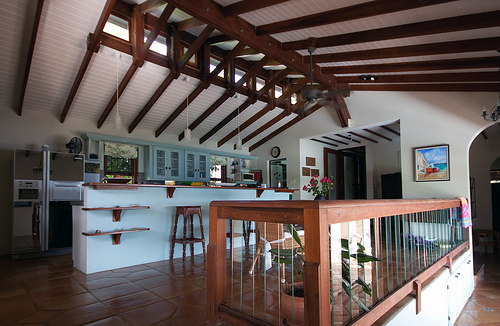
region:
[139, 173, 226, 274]
brown stool in front of counter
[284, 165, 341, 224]
red flowers and green leaves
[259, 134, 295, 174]
clock on white wall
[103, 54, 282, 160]
white lights hanging from ceiling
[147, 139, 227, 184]
cupboard doors with glass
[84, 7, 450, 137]
wood beams on ceiling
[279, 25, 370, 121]
black fan hanging from ceiling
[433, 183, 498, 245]
colored towel draped over wood divider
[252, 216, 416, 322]
green plant in clay pot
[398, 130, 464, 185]
boat and water picture on wall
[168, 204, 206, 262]
wooden stool by bar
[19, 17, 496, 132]
wood trusses on ceiling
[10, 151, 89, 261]
refrigerator/freezer behind bar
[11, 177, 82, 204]
reflection of appliances in the refrigerator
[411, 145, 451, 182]
painting on white wall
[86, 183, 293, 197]
bar top supported by wooden wedges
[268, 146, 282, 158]
clock on white wall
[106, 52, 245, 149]
three pendant light fixtures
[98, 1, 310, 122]
skylights above bar area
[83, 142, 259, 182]
white and glass cabinets behind bar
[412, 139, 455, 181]
artwork on the wall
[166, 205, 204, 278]
stool by kitchen counter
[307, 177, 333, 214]
red flowers in a vase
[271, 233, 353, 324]
potted plant by railing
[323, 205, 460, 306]
glass railing with wood trim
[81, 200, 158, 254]
two shelves on side of kitchen island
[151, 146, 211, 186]
kitchen cabinets on wall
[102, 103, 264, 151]
lights hanging from ceiling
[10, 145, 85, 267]
stainless steel refrigerator in kitchen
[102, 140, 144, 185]
window in kitchen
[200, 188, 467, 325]
brown railing with bars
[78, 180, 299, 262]
white island in kitchen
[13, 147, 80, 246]
silver fridge in kitchen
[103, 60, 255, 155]
three white lights hanging from ceiling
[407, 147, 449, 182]
painting on hanging on wall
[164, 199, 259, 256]
stools at white kitchen island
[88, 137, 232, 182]
windows in the kitchen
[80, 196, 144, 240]
shelves on white kitchen island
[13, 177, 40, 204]
ice maker on silver fridge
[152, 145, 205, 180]
two cabinets between windows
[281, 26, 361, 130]
A Cailing Fan In Motion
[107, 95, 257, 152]
Three Hanging White Lights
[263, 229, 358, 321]
A Plant in a Terra Cotta Pot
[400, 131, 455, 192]
A Colorful Painting on the Wall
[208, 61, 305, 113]
Sky Lights with Thick Wooden Frames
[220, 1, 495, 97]
Thick Dark Wooden Rafters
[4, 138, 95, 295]
A Stainless Steel Refrigerator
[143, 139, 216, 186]
White Cupboards with Glass Doors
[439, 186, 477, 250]
An Orange and Red Towel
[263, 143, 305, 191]
A Wall Clock over an Entry Way